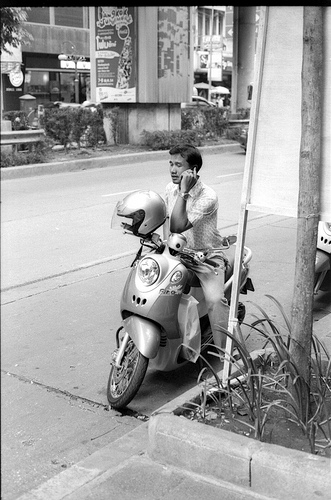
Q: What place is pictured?
A: It is a roadway.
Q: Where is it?
A: This is at the roadway.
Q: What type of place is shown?
A: It is a roadway.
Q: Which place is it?
A: It is a roadway.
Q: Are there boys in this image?
A: No, there are no boys.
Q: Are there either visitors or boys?
A: No, there are no boys or visitors.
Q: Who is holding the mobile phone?
A: The guy is holding the mobile phone.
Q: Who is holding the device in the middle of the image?
A: The guy is holding the mobile phone.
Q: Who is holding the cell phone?
A: The guy is holding the mobile phone.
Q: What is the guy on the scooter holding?
A: The guy is holding the cell phone.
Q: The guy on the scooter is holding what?
A: The guy is holding the cell phone.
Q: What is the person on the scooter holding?
A: The guy is holding the cell phone.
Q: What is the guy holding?
A: The guy is holding the cell phone.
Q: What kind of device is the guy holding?
A: The guy is holding the cellphone.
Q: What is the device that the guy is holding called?
A: The device is a cell phone.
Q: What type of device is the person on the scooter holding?
A: The guy is holding the cellphone.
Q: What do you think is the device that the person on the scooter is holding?
A: The device is a cell phone.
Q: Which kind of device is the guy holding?
A: The guy is holding the cellphone.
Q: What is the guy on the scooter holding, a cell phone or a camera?
A: The guy is holding a cell phone.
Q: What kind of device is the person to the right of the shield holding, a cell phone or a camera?
A: The guy is holding a cell phone.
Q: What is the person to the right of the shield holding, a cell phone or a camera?
A: The guy is holding a cell phone.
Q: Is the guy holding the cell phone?
A: Yes, the guy is holding the cell phone.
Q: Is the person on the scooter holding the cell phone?
A: Yes, the guy is holding the cell phone.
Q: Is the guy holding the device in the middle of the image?
A: Yes, the guy is holding the cell phone.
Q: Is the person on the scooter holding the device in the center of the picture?
A: Yes, the guy is holding the cell phone.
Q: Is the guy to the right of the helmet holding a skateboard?
A: No, the guy is holding the cell phone.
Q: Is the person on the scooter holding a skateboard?
A: No, the guy is holding the cell phone.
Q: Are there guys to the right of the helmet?
A: Yes, there is a guy to the right of the helmet.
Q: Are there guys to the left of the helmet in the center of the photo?
A: No, the guy is to the right of the helmet.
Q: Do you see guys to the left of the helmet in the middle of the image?
A: No, the guy is to the right of the helmet.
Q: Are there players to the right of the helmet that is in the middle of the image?
A: No, there is a guy to the right of the helmet.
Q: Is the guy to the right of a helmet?
A: Yes, the guy is to the right of a helmet.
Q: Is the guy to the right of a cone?
A: No, the guy is to the right of a helmet.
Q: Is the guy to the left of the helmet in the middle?
A: No, the guy is to the right of the helmet.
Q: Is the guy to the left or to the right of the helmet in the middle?
A: The guy is to the right of the helmet.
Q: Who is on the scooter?
A: The guy is on the scooter.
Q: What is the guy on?
A: The guy is on the scooter.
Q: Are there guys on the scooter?
A: Yes, there is a guy on the scooter.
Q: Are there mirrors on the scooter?
A: No, there is a guy on the scooter.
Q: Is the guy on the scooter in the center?
A: Yes, the guy is on the scooter.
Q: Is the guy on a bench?
A: No, the guy is on the scooter.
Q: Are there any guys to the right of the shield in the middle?
A: Yes, there is a guy to the right of the shield.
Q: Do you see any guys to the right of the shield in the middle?
A: Yes, there is a guy to the right of the shield.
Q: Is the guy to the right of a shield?
A: Yes, the guy is to the right of a shield.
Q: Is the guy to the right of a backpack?
A: No, the guy is to the right of a shield.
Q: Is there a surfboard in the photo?
A: No, there are no surfboards.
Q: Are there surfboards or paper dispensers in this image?
A: No, there are no surfboards or paper dispensers.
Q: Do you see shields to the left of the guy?
A: Yes, there is a shield to the left of the guy.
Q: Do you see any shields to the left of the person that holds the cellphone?
A: Yes, there is a shield to the left of the guy.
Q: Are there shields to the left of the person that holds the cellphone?
A: Yes, there is a shield to the left of the guy.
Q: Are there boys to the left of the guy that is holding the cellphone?
A: No, there is a shield to the left of the guy.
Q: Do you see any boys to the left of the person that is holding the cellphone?
A: No, there is a shield to the left of the guy.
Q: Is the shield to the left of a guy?
A: Yes, the shield is to the left of a guy.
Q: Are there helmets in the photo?
A: Yes, there is a helmet.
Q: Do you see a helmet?
A: Yes, there is a helmet.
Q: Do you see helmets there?
A: Yes, there is a helmet.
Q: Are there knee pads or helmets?
A: Yes, there is a helmet.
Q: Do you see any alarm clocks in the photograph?
A: No, there are no alarm clocks.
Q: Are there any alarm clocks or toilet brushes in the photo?
A: No, there are no alarm clocks or toilet brushes.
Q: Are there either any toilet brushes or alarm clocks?
A: No, there are no alarm clocks or toilet brushes.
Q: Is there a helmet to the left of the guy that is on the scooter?
A: Yes, there is a helmet to the left of the guy.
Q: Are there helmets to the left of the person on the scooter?
A: Yes, there is a helmet to the left of the guy.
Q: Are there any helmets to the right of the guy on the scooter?
A: No, the helmet is to the left of the guy.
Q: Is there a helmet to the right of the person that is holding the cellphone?
A: No, the helmet is to the left of the guy.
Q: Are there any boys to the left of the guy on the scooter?
A: No, there is a helmet to the left of the guy.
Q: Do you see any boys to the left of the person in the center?
A: No, there is a helmet to the left of the guy.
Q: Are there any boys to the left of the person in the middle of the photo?
A: No, there is a helmet to the left of the guy.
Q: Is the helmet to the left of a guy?
A: Yes, the helmet is to the left of a guy.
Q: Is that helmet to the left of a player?
A: No, the helmet is to the left of a guy.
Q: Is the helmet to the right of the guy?
A: No, the helmet is to the left of the guy.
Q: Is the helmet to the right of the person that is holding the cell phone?
A: No, the helmet is to the left of the guy.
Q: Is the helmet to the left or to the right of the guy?
A: The helmet is to the left of the guy.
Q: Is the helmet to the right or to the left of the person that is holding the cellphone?
A: The helmet is to the left of the guy.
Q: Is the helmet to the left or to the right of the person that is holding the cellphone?
A: The helmet is to the left of the guy.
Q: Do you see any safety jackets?
A: No, there are no safety jackets.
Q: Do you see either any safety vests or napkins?
A: No, there are no safety vests or napkins.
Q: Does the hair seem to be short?
A: Yes, the hair is short.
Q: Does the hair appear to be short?
A: Yes, the hair is short.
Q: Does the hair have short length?
A: Yes, the hair is short.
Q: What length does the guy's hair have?
A: The hair has short length.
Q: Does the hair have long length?
A: No, the hair is short.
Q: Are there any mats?
A: No, there are no mats.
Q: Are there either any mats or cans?
A: No, there are no mats or cans.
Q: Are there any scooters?
A: Yes, there is a scooter.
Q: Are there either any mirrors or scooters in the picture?
A: Yes, there is a scooter.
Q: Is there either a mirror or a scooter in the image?
A: Yes, there is a scooter.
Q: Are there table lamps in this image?
A: No, there are no table lamps.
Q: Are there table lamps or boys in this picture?
A: No, there are no table lamps or boys.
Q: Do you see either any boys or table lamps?
A: No, there are no table lamps or boys.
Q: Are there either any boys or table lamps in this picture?
A: No, there are no table lamps or boys.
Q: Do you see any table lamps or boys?
A: No, there are no table lamps or boys.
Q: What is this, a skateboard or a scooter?
A: This is a scooter.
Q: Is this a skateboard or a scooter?
A: This is a scooter.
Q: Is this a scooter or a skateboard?
A: This is a scooter.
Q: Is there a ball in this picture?
A: No, there are no balls.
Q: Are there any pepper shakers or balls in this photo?
A: No, there are no balls or pepper shakers.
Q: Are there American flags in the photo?
A: No, there are no American flags.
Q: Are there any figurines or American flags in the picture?
A: No, there are no American flags or figurines.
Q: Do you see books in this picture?
A: No, there are no books.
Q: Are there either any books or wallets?
A: No, there are no books or wallets.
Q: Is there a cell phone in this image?
A: Yes, there is a cell phone.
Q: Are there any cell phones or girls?
A: Yes, there is a cell phone.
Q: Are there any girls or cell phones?
A: Yes, there is a cell phone.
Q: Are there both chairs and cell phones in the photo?
A: No, there is a cell phone but no chairs.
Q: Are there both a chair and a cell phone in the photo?
A: No, there is a cell phone but no chairs.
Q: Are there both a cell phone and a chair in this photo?
A: No, there is a cell phone but no chairs.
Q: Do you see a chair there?
A: No, there are no chairs.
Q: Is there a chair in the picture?
A: No, there are no chairs.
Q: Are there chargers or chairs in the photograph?
A: No, there are no chairs or chargers.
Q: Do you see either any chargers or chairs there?
A: No, there are no chairs or chargers.